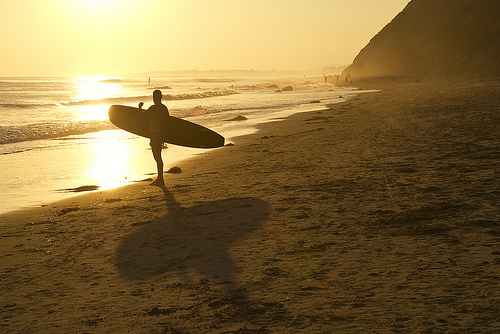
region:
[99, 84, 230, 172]
surf board carried by surfer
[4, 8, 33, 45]
white clouds in blue sky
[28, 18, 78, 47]
white clouds in blue sky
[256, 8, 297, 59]
white clouds in blue sky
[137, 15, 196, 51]
white clouds in blue sky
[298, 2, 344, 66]
white clouds in blue sky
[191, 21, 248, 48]
white clouds in blue sky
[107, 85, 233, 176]
surfer carrying board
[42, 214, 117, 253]
wet sand on the beach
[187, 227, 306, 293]
wet sand on the beach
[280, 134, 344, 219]
wet sand on the beach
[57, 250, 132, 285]
wet sand on the beach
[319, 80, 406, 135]
wet sand on the beach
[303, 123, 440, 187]
wet sand on the beach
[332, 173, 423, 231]
wet sand on the beach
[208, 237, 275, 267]
wet sand on the beach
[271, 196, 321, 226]
wet sand on the beach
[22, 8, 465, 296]
Beautiful beach day with a lovely sunset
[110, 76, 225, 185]
man carrying a surfboard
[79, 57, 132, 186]
sun reflecting off the ocean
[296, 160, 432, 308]
footprints in the sand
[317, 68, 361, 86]
people on the beach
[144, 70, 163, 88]
paddle surfer in the water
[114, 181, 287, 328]
shadow of the man with the surfboard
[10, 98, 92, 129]
waves in the ocean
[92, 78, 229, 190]
man posing for a photo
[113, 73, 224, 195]
man ready to surf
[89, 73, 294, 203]
a man carrying his surfboard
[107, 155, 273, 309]
shadow on the ground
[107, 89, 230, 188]
Man holding surfboard.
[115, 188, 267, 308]
Shadow of man and surfboard.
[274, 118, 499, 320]
Footprints in sand on beach.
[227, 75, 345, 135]
Multiple rocks in water.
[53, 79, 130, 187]
Sun reflecting on water.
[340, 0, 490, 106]
Big mountain on beach.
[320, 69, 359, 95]
People standing on beach.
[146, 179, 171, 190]
Man's bare feet.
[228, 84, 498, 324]
Sand on beach.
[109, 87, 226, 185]
Shirtless surfer standing on beach.